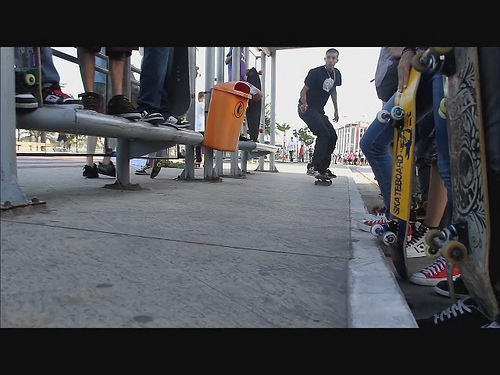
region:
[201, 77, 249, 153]
The plastic trash can is orange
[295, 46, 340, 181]
The man is riding a skateboard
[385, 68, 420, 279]
The boy on the right is holding a yellow and black skateboard.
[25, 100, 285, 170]
The railing is silver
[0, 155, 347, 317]
The side walk is gray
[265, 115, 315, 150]
The trees are far in the distance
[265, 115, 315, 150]
The trees are green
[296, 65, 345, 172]
The skateboarder is wearing a black shirt and black pants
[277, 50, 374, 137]
The sky is white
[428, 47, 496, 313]
The front skateboard is black and white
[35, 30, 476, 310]
skateboarder riding down a flat path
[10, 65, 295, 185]
people standing on silver metal railing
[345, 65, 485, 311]
people standing along the side of the curb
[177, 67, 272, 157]
orange container with opening on top hanging from railing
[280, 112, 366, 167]
pedestrians and building in background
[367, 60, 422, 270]
person holding skateboard that says skateboard on it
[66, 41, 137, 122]
two thin legs on black clunky shoes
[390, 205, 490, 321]
white, red and black sneakers with laces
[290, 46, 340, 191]
skateboarder in dark clothing leaning forward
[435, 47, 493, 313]
skateboard with detailed drawing including swirls and and circles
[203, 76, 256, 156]
An orange receptacle.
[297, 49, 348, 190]
A boy riding a skateboard.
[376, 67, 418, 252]
A yellow skateboard with a logo on it.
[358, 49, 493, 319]
Skateboarders stand along the sidewalk.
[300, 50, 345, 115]
The boy is wearing a black shirt.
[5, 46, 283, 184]
People standing on a metal bench.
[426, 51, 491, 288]
A drawing on the back of the skateboard.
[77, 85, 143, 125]
A pair of black tennis shoes with black laces.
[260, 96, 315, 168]
Trees in the background.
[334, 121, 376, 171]
Multi floor building in the background.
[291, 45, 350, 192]
man on a skateboard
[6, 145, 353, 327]
concrete sidewalk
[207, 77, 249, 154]
a small orange trash can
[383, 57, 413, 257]
a yellow skateboard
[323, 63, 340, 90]
a man's metal chain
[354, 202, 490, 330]
several skate shoes lined up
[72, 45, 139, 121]
a person wearing black shorts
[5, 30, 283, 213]
a metal grey railing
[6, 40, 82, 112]
a skater standing on a platform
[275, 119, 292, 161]
a palm tree in the background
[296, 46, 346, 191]
The skate boarder is wearing black pants and shirt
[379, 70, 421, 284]
The boy on the right is holding a yellow and black skateboard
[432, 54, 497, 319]
The boy on the right is holding a white and black skateboard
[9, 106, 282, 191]
The metal railing is silver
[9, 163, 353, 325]
The sidewalk is gray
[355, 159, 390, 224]
The street is grey with a yellow stripe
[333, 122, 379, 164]
The building in the back is white and red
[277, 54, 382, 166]
The sky is light blue